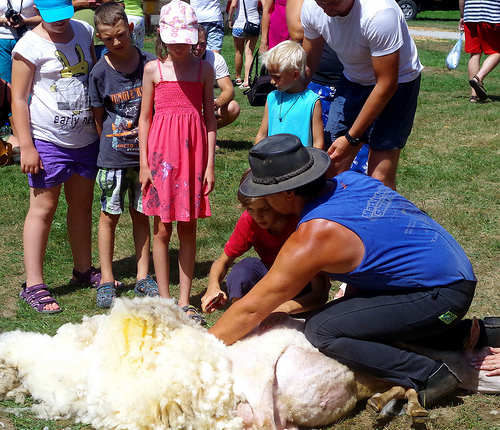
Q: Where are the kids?
A: On the grass.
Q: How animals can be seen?
A: 1.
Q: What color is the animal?
A: White.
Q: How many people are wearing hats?
A: 3.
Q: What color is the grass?
A: Green.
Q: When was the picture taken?
A: Daytime.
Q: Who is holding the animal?
A: A man.